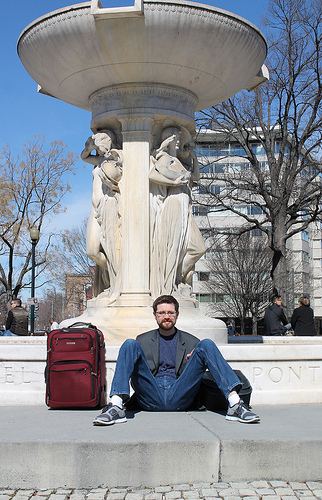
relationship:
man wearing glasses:
[91, 292, 263, 423] [154, 309, 178, 315]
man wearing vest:
[1, 295, 31, 335] [8, 305, 30, 333]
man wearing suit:
[263, 293, 289, 337] [261, 304, 289, 333]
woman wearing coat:
[285, 293, 319, 336] [289, 305, 315, 334]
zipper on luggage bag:
[87, 367, 101, 376] [38, 319, 109, 412]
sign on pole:
[26, 293, 41, 308] [28, 238, 35, 334]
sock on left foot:
[227, 388, 240, 407] [225, 391, 257, 422]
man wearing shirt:
[91, 292, 263, 423] [153, 328, 178, 375]